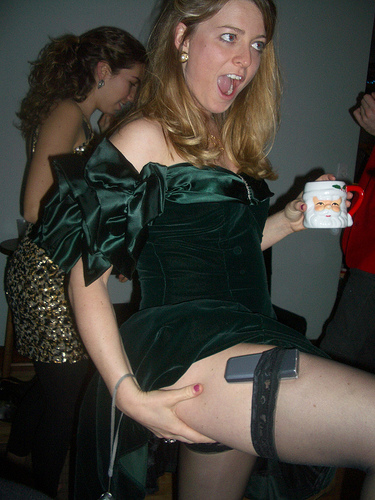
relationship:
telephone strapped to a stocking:
[222, 344, 304, 385] [246, 345, 371, 500]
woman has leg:
[34, 0, 374, 499] [149, 330, 374, 499]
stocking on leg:
[246, 345, 371, 500] [149, 330, 374, 499]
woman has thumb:
[34, 0, 374, 499] [167, 381, 206, 409]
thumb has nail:
[167, 381, 206, 409] [192, 382, 201, 392]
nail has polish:
[192, 382, 201, 392] [193, 382, 201, 396]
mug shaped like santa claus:
[300, 177, 365, 232] [299, 178, 348, 231]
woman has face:
[34, 0, 374, 499] [166, 1, 269, 120]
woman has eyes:
[34, 0, 374, 499] [217, 30, 267, 55]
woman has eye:
[34, 0, 374, 499] [217, 31, 241, 46]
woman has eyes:
[34, 0, 374, 499] [250, 36, 268, 52]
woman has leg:
[34, 0, 374, 499] [169, 430, 264, 498]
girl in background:
[5, 19, 149, 498] [2, 1, 197, 439]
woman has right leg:
[34, 0, 374, 499] [141, 303, 375, 498]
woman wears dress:
[34, 0, 374, 499] [30, 128, 340, 499]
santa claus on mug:
[299, 178, 348, 231] [300, 177, 365, 232]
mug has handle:
[300, 177, 365, 232] [344, 184, 365, 217]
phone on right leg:
[222, 344, 304, 385] [141, 303, 375, 498]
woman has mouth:
[34, 0, 374, 499] [211, 69, 248, 102]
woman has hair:
[34, 0, 374, 499] [141, 2, 283, 186]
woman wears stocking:
[34, 0, 374, 499] [246, 345, 371, 500]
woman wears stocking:
[34, 0, 374, 499] [175, 437, 254, 499]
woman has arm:
[34, 0, 374, 499] [52, 127, 218, 450]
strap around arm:
[105, 369, 137, 479] [52, 127, 218, 450]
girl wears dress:
[5, 19, 149, 498] [5, 108, 91, 368]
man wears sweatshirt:
[313, 53, 375, 365] [339, 125, 375, 274]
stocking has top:
[246, 345, 371, 500] [243, 343, 292, 463]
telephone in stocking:
[222, 344, 304, 385] [246, 345, 371, 500]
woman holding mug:
[34, 0, 374, 499] [300, 177, 365, 232]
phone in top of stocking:
[222, 344, 304, 385] [246, 345, 371, 500]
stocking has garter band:
[246, 345, 371, 500] [247, 340, 292, 463]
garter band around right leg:
[247, 340, 292, 463] [141, 303, 375, 498]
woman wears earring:
[34, 0, 374, 499] [175, 49, 190, 65]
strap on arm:
[105, 369, 137, 479] [52, 127, 218, 450]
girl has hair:
[5, 19, 149, 498] [11, 19, 150, 164]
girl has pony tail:
[5, 19, 149, 498] [12, 31, 83, 163]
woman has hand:
[34, 0, 374, 499] [123, 381, 218, 448]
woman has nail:
[34, 0, 374, 499] [192, 382, 201, 392]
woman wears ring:
[34, 0, 374, 499] [163, 434, 180, 444]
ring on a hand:
[163, 434, 180, 444] [123, 381, 218, 448]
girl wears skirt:
[5, 19, 149, 498] [2, 225, 92, 367]